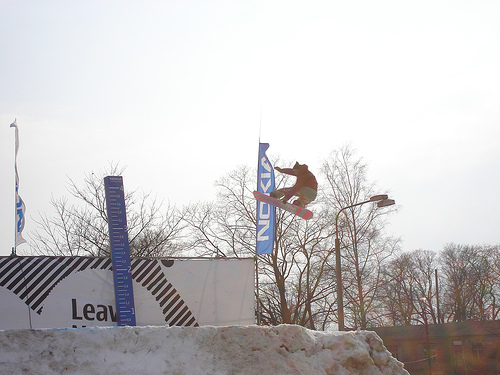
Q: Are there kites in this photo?
A: No, there are no kites.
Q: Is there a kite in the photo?
A: No, there are no kites.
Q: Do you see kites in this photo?
A: No, there are no kites.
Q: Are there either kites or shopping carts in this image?
A: No, there are no kites or shopping carts.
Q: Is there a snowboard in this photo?
A: Yes, there is a snowboard.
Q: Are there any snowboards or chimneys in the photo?
A: Yes, there is a snowboard.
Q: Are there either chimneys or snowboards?
A: Yes, there is a snowboard.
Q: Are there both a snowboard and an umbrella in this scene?
A: No, there is a snowboard but no umbrellas.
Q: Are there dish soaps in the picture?
A: No, there are no dish soaps.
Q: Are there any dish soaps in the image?
A: No, there are no dish soaps.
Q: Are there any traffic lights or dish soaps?
A: No, there are no dish soaps or traffic lights.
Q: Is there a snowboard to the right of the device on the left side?
A: Yes, there is a snowboard to the right of the device.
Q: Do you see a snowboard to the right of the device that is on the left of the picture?
A: Yes, there is a snowboard to the right of the device.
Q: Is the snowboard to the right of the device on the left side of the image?
A: Yes, the snowboard is to the right of the device.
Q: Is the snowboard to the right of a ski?
A: No, the snowboard is to the right of the device.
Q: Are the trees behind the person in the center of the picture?
A: Yes, the trees are behind the person.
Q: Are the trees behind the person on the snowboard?
A: Yes, the trees are behind the person.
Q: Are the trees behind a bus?
A: No, the trees are behind the person.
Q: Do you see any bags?
A: No, there are no bags.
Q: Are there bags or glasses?
A: No, there are no bags or glasses.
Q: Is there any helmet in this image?
A: No, there are no helmets.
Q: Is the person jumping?
A: Yes, the person is jumping.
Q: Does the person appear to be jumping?
A: Yes, the person is jumping.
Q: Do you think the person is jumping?
A: Yes, the person is jumping.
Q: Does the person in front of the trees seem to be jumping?
A: Yes, the person is jumping.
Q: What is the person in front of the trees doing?
A: The person is jumping.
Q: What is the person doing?
A: The person is jumping.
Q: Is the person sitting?
A: No, the person is jumping.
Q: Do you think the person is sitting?
A: No, the person is jumping.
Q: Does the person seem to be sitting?
A: No, the person is jumping.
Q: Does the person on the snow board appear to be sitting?
A: No, the person is jumping.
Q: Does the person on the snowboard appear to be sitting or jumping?
A: The person is jumping.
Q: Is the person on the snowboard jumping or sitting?
A: The person is jumping.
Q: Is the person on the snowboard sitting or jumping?
A: The person is jumping.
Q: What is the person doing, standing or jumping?
A: The person is jumping.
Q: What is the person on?
A: The person is on the snowboard.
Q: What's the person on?
A: The person is on the snowboard.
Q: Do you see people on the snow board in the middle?
A: Yes, there is a person on the snow board.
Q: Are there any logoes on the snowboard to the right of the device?
A: No, there is a person on the snowboard.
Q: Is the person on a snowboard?
A: Yes, the person is on a snowboard.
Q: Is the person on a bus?
A: No, the person is on a snowboard.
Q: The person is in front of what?
A: The person is in front of the trees.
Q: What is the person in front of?
A: The person is in front of the trees.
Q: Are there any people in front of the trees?
A: Yes, there is a person in front of the trees.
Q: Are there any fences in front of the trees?
A: No, there is a person in front of the trees.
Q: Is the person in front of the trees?
A: Yes, the person is in front of the trees.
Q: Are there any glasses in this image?
A: No, there are no glasses.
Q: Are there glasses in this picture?
A: No, there are no glasses.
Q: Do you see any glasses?
A: No, there are no glasses.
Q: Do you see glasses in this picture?
A: No, there are no glasses.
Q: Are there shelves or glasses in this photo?
A: No, there are no glasses or shelves.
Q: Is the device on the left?
A: Yes, the device is on the left of the image.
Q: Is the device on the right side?
A: No, the device is on the left of the image.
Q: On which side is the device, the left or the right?
A: The device is on the left of the image.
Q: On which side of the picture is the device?
A: The device is on the left of the image.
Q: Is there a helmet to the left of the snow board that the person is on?
A: No, there is a device to the left of the snowboard.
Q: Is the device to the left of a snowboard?
A: Yes, the device is to the left of a snowboard.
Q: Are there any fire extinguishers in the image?
A: No, there are no fire extinguishers.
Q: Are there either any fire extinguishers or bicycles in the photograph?
A: No, there are no fire extinguishers or bicycles.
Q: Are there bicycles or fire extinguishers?
A: No, there are no fire extinguishers or bicycles.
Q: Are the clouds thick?
A: Yes, the clouds are thick.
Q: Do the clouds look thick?
A: Yes, the clouds are thick.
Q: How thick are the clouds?
A: The clouds are thick.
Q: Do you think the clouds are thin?
A: No, the clouds are thick.